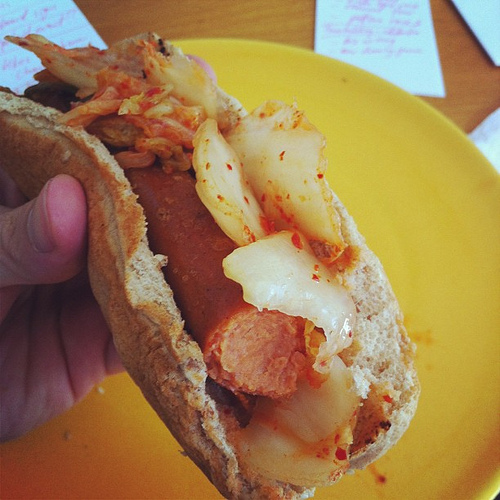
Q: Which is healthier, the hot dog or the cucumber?
A: The cucumber is healthier than the hot dog.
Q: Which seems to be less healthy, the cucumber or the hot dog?
A: The hot dog is less healthy than the cucumber.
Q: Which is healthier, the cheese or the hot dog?
A: The cheese is healthier than the hot dog.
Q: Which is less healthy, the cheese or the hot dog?
A: The hot dog is less healthy than the cheese.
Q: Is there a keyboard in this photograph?
A: No, there are no keyboards.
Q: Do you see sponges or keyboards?
A: No, there are no keyboards or sponges.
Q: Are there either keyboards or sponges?
A: No, there are no keyboards or sponges.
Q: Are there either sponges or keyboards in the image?
A: No, there are no keyboards or sponges.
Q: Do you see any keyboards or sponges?
A: No, there are no keyboards or sponges.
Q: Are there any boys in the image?
A: No, there are no boys.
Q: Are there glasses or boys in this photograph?
A: No, there are no boys or glasses.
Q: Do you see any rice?
A: No, there is no rice.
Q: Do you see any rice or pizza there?
A: No, there are no rice or pizzas.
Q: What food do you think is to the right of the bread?
A: The food is a sausage.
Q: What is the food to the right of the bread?
A: The food is a sausage.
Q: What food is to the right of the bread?
A: The food is a sausage.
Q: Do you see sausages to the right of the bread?
A: Yes, there is a sausage to the right of the bread.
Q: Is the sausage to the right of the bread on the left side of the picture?
A: Yes, the sausage is to the right of the bread.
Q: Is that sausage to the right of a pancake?
A: No, the sausage is to the right of the bread.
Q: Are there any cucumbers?
A: Yes, there is a cucumber.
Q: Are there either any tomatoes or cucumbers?
A: Yes, there is a cucumber.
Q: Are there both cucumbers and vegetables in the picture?
A: Yes, there are both a cucumber and vegetables.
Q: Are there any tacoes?
A: No, there are no tacoes.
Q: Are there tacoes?
A: No, there are no tacoes.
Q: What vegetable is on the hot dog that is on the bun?
A: The vegetable is a cucumber.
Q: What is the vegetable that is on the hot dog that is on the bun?
A: The vegetable is a cucumber.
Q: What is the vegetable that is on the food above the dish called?
A: The vegetable is a cucumber.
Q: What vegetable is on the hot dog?
A: The vegetable is a cucumber.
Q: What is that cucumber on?
A: The cucumber is on the hot dog.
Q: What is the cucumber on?
A: The cucumber is on the hot dog.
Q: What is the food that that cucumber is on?
A: The food is a hot dog.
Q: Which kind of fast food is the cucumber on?
A: The cucumber is on the hot dog.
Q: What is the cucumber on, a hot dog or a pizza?
A: The cucumber is on a hot dog.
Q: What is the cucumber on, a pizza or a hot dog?
A: The cucumber is on a hot dog.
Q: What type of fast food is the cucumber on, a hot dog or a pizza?
A: The cucumber is on a hot dog.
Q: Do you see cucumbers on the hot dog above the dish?
A: Yes, there is a cucumber on the hot dog.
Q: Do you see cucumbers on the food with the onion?
A: Yes, there is a cucumber on the hot dog.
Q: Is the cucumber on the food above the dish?
A: Yes, the cucumber is on the hot dog.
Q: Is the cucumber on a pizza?
A: No, the cucumber is on the hot dog.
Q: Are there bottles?
A: No, there are no bottles.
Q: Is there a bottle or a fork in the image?
A: No, there are no bottles or forks.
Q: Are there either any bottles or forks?
A: No, there are no bottles or forks.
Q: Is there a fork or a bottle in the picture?
A: No, there are no bottles or forks.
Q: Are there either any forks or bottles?
A: No, there are no bottles or forks.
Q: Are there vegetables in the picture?
A: Yes, there are vegetables.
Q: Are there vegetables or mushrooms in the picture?
A: Yes, there are vegetables.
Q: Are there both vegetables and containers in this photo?
A: No, there are vegetables but no containers.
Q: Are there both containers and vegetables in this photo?
A: No, there are vegetables but no containers.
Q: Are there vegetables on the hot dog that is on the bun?
A: Yes, there are vegetables on the hot dog.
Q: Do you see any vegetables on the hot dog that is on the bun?
A: Yes, there are vegetables on the hot dog.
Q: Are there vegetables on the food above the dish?
A: Yes, there are vegetables on the hot dog.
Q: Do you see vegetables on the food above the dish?
A: Yes, there are vegetables on the hot dog.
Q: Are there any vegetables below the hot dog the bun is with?
A: Yes, there are vegetables below the hot dog.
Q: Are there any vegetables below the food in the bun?
A: Yes, there are vegetables below the hot dog.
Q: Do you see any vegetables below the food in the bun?
A: Yes, there are vegetables below the hot dog.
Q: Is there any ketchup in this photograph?
A: Yes, there is ketchup.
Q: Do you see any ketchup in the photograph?
A: Yes, there is ketchup.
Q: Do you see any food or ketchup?
A: Yes, there is ketchup.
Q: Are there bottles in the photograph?
A: No, there are no bottles.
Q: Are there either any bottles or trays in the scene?
A: No, there are no bottles or trays.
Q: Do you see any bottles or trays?
A: No, there are no bottles or trays.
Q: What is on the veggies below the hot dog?
A: The ketchup is on the veggies.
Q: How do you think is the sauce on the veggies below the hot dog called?
A: The sauce is ketchup.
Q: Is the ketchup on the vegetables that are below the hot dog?
A: Yes, the ketchup is on the vegetables.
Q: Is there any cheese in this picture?
A: Yes, there is cheese.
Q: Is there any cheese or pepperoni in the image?
A: Yes, there is cheese.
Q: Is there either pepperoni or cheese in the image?
A: Yes, there is cheese.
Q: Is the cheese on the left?
A: Yes, the cheese is on the left of the image.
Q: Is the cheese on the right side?
A: No, the cheese is on the left of the image.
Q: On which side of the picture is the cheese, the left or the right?
A: The cheese is on the left of the image.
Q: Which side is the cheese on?
A: The cheese is on the left of the image.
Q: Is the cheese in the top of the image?
A: Yes, the cheese is in the top of the image.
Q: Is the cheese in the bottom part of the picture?
A: No, the cheese is in the top of the image.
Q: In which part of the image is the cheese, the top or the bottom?
A: The cheese is in the top of the image.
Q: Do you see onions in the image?
A: Yes, there is an onion.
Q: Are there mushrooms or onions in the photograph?
A: Yes, there is an onion.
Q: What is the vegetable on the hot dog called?
A: The vegetable is an onion.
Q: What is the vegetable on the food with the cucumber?
A: The vegetable is an onion.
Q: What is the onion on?
A: The onion is on the hot dog.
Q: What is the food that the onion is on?
A: The food is a hot dog.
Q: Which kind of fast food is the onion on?
A: The onion is on the hot dog.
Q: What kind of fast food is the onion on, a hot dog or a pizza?
A: The onion is on a hot dog.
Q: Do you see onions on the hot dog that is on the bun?
A: Yes, there is an onion on the hot dog.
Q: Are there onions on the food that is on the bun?
A: Yes, there is an onion on the hot dog.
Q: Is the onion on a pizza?
A: No, the onion is on the hot dog.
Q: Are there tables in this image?
A: Yes, there is a table.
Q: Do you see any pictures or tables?
A: Yes, there is a table.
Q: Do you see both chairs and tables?
A: No, there is a table but no chairs.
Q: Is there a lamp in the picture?
A: No, there are no lamps.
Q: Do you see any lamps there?
A: No, there are no lamps.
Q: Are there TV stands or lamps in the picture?
A: No, there are no lamps or TV stands.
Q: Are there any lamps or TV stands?
A: No, there are no lamps or TV stands.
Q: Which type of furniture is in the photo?
A: The furniture is a table.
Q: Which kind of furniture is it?
A: The piece of furniture is a table.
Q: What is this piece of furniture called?
A: That is a table.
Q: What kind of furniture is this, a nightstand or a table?
A: That is a table.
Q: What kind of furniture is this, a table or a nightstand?
A: That is a table.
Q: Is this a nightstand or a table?
A: This is a table.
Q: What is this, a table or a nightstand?
A: This is a table.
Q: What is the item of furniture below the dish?
A: The piece of furniture is a table.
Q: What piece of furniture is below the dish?
A: The piece of furniture is a table.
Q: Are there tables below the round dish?
A: Yes, there is a table below the dish.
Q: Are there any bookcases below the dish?
A: No, there is a table below the dish.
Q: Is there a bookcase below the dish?
A: No, there is a table below the dish.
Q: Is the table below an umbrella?
A: No, the table is below a dish.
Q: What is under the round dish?
A: The table is under the dish.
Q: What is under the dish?
A: The table is under the dish.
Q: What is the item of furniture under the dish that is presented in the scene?
A: The piece of furniture is a table.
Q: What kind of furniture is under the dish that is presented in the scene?
A: The piece of furniture is a table.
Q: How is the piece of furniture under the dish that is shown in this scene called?
A: The piece of furniture is a table.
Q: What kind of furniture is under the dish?
A: The piece of furniture is a table.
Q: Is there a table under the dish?
A: Yes, there is a table under the dish.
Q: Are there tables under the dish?
A: Yes, there is a table under the dish.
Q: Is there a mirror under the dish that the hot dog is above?
A: No, there is a table under the dish.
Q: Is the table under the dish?
A: Yes, the table is under the dish.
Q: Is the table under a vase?
A: No, the table is under the dish.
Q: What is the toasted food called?
A: The food is a bun.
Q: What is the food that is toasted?
A: The food is a bun.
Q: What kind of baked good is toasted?
A: The baked good is a bun.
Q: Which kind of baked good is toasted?
A: The baked good is a bun.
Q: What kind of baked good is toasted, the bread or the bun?
A: The bun is toasted.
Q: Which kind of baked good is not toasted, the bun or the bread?
A: The bread is not toasted.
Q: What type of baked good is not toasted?
A: The baked good is a bread.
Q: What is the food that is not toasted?
A: The food is a bread.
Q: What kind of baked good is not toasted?
A: The baked good is a bread.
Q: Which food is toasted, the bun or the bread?
A: The bun is toasted.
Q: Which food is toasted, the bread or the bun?
A: The bun is toasted.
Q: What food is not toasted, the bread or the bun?
A: The bread is not toasted.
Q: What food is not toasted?
A: The food is a bread.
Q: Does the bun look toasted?
A: Yes, the bun is toasted.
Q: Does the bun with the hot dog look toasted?
A: Yes, the bun is toasted.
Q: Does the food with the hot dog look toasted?
A: Yes, the bun is toasted.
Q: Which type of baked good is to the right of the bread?
A: The food is a bun.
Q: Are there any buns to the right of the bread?
A: Yes, there is a bun to the right of the bread.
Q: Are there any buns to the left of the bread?
A: No, the bun is to the right of the bread.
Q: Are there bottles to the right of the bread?
A: No, there is a bun to the right of the bread.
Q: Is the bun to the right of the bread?
A: Yes, the bun is to the right of the bread.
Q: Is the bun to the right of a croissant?
A: No, the bun is to the right of the bread.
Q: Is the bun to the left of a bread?
A: No, the bun is to the right of a bread.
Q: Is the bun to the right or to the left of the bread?
A: The bun is to the right of the bread.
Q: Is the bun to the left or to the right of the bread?
A: The bun is to the right of the bread.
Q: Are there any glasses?
A: No, there are no glasses.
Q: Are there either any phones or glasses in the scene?
A: No, there are no glasses or phones.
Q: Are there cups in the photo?
A: No, there are no cups.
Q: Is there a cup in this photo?
A: No, there are no cups.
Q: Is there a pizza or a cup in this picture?
A: No, there are no cups or pizzas.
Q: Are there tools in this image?
A: No, there are no tools.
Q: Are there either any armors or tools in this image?
A: No, there are no tools or armors.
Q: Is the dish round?
A: Yes, the dish is round.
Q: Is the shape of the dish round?
A: Yes, the dish is round.